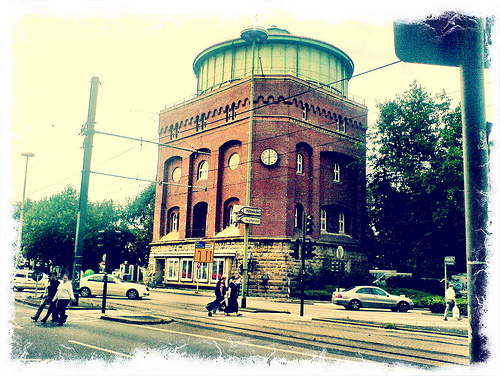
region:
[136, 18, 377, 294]
oddly shaped building on the corner of a block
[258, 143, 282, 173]
clock on the front of the building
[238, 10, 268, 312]
street signs on tall green pole with circular object on top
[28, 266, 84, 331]
two people crossing the street going left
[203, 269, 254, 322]
two people crossing the street going right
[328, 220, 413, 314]
car alongside the building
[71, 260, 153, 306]
car entering the intersection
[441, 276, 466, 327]
man walking away carrying something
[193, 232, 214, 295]
street sign showing directions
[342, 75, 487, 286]
trees alongside the buiding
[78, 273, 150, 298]
A white car on the street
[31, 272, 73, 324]
People walking across the street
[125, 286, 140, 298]
The front tire of the car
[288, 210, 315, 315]
Traffic lights by the street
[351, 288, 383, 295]
Windows on the car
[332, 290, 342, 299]
Tail lights behind the car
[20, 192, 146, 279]
Trees near the building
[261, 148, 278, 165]
A clock on the building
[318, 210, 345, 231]
Windows on the side of the building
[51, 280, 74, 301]
The woman is wearing a white sweater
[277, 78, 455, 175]
Black telephone wires above the street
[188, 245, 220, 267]
A small yellow sign by the building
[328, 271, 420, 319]
A small grey car driving on the street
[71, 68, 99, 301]
A large wooden telephone pole by the street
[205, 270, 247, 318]
Pedestrians crossing the road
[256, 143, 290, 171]
A large circular clock on the red building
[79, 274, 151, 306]
A small beige car on the road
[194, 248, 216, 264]
Black arrows painted on the yellow sign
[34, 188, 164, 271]
Healthy green trees growing near the building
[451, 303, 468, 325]
A white grocery bag in the man's hand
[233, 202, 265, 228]
The sign is white.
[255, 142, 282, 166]
The clock has a white face.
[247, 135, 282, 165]
The clock is on the building.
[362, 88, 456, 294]
The tree is green.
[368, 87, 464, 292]
The tree is leafy.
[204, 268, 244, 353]
The people are walking.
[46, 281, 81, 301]
The person has a white shirt.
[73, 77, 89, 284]
The pole is grey.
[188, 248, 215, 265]
The sign is yellow.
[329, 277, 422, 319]
The car is parked.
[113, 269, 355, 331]
people walking across a street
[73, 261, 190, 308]
white car on the street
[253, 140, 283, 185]
large clock on the side of a brick building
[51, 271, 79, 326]
woman in a white sweatshirt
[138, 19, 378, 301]
large brick building with a round top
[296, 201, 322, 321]
traffic light on a pole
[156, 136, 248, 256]
three brick architectural archways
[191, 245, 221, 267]
yellow road sign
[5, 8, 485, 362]
several people and cars near a large brick building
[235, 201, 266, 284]
directional street signs